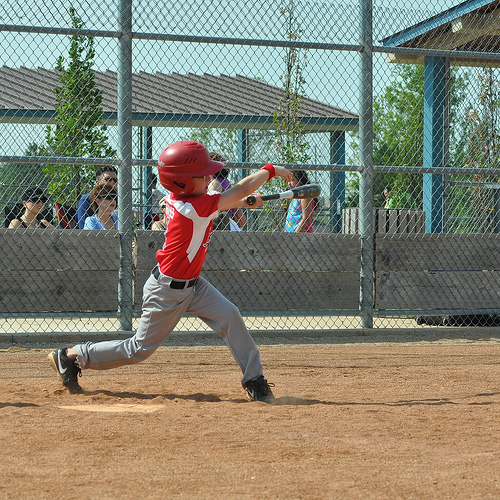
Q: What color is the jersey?
A: Red and white.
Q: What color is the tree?
A: Green.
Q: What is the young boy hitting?
A: A ball.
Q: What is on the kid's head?
A: Helmet.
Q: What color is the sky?
A: Blue.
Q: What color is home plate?
A: White.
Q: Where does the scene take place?
A: At a baseball game.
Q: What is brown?
A: Dirt.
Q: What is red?
A: Helmet.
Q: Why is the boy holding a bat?
A: To hit the ball.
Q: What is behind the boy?
A: Fence.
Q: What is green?
A: Trees.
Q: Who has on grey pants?
A: The batter.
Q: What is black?
A: Sneakers.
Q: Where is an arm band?
A: On boy's right arm.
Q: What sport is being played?
A: Baseball.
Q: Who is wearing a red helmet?
A: The batter.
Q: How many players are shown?
A: One.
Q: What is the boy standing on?
A: Dirt.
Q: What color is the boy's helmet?
A: Red.